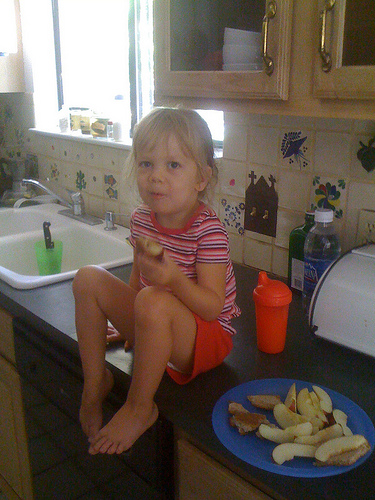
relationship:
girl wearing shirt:
[103, 110, 232, 383] [132, 207, 240, 286]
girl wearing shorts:
[103, 110, 232, 383] [182, 318, 227, 384]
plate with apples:
[218, 371, 369, 478] [272, 399, 334, 439]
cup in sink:
[32, 242, 67, 274] [9, 204, 105, 264]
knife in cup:
[40, 223, 61, 245] [32, 242, 67, 274]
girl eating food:
[103, 110, 232, 383] [132, 234, 168, 265]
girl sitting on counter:
[103, 110, 232, 383] [71, 284, 213, 403]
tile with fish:
[42, 144, 130, 204] [102, 172, 125, 208]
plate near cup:
[218, 371, 369, 478] [252, 271, 294, 357]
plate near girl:
[218, 371, 369, 478] [103, 110, 232, 383]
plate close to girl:
[218, 371, 369, 478] [103, 110, 232, 383]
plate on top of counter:
[218, 371, 369, 478] [71, 284, 213, 403]